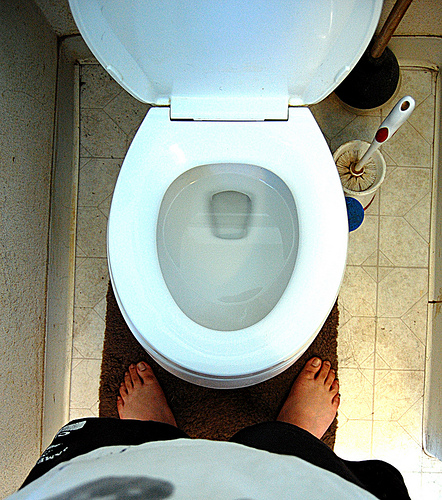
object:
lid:
[67, 0, 379, 112]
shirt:
[10, 438, 387, 499]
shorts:
[20, 418, 408, 500]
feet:
[278, 358, 340, 440]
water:
[160, 188, 286, 309]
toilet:
[84, 39, 379, 393]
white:
[26, 407, 86, 500]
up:
[207, 45, 288, 90]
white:
[125, 229, 151, 323]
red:
[375, 125, 388, 143]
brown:
[372, 88, 375, 100]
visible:
[83, 370, 367, 429]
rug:
[98, 278, 343, 456]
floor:
[68, 65, 434, 460]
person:
[2, 357, 411, 498]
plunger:
[335, 1, 419, 111]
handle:
[372, 0, 411, 59]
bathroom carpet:
[98, 281, 339, 455]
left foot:
[114, 360, 178, 429]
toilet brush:
[336, 93, 415, 193]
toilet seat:
[106, 108, 351, 378]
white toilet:
[65, 0, 392, 392]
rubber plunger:
[338, 44, 399, 110]